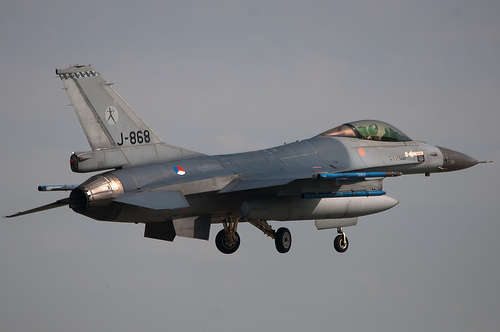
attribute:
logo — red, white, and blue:
[159, 161, 234, 186]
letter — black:
[117, 132, 124, 145]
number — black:
[142, 128, 151, 143]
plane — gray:
[44, 58, 499, 256]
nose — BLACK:
[436, 149, 488, 174]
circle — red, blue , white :
[166, 161, 193, 181]